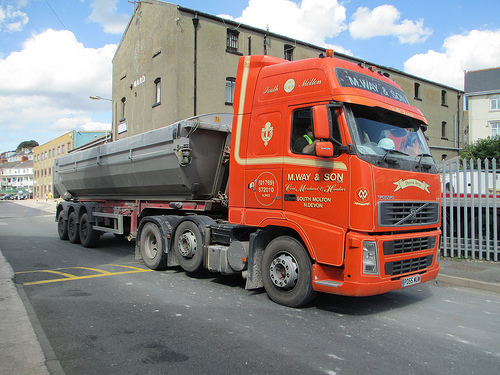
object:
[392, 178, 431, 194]
logo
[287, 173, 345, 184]
trucking company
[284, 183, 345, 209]
location text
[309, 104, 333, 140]
mirrors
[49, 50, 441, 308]
truck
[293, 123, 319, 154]
people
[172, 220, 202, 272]
tires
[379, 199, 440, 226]
grilles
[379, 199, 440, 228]
ventilation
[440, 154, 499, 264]
fence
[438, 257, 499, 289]
sidewalk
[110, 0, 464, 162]
building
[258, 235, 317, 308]
tire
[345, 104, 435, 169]
windshield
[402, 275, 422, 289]
license plate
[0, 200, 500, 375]
road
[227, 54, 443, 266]
cab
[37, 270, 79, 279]
lines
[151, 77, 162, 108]
windows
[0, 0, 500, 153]
sky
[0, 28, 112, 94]
clouds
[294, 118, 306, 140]
passenger seat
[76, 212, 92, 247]
wheels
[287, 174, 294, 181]
letters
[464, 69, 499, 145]
building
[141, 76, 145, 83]
letters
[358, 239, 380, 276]
headlight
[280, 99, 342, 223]
door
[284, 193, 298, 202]
door handle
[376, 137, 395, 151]
hat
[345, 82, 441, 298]
front